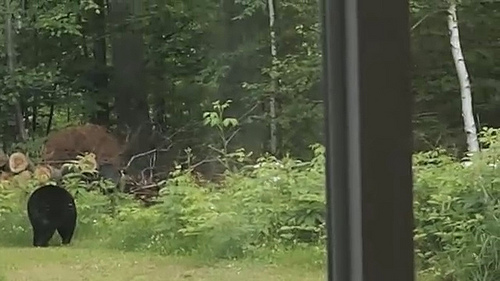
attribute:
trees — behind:
[24, 7, 329, 180]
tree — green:
[8, 0, 57, 65]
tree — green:
[30, 0, 77, 68]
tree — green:
[53, 0, 83, 64]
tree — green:
[77, 0, 109, 73]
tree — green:
[39, 75, 79, 131]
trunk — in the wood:
[265, 10, 286, 69]